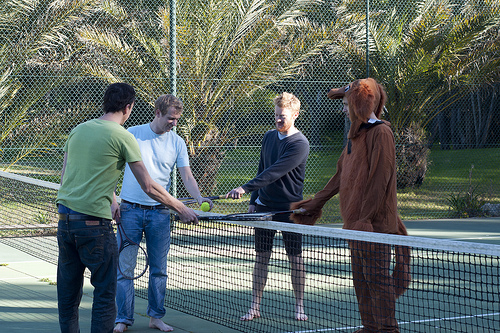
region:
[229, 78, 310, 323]
Red headed man with beard.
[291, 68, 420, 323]
Man dressed up in a dog costume.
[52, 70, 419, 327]
Four guys having a casual meet up.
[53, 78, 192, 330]
Man in short sleeve light green tee shirt.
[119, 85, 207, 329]
Man in short sleeve light blue tee shirt.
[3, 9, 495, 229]
Short palm bushes in the background.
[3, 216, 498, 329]
Green tennis court with white stripes.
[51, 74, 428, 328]
A casual game of tennis playing in bare feet.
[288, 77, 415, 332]
Dark brown dog costume for mascot.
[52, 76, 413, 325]
Four guys goofing around with a tennis ball.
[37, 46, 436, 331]
four people standing on a tennis court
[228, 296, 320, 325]
no shoes on the feet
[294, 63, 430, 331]
person in an animal costume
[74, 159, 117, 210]
wrinkles on the shirt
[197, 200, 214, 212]
small yellow tennis ball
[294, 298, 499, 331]
white line on the court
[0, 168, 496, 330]
white and black net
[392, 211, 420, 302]
brown tail of the costume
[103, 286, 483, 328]
shadows on the court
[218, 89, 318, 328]
man who is pointing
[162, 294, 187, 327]
part of a court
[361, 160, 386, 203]
part of a costume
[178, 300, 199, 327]
part of a cpouert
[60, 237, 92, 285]
part of a ;long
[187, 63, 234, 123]
part of a fence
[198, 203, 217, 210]
A tennis ball by the net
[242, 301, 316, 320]
This man has no shoes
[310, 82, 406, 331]
A man in a dog costume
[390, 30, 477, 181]
A tree by the tennis court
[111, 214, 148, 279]
A black racket in the man's hands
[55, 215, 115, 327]
This man is wearing pants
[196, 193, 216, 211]
A tennis ball in the man's left hand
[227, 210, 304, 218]
A tennis racket on the net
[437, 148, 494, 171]
Grass by the tree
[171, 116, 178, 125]
The nose of the man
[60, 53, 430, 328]
an unusual tennis game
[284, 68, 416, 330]
this tennis player is wearing a costume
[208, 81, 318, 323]
this tennis player does not have shoes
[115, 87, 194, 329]
this tennis player is barefoot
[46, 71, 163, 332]
this tennis player is wearing a green shirt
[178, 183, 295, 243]
the tennis players have their racquets on the net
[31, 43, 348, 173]
this tennis court has a fence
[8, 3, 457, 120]
trees near the tennis court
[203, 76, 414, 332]
these two players are on the same team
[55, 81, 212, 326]
these two players are teammates